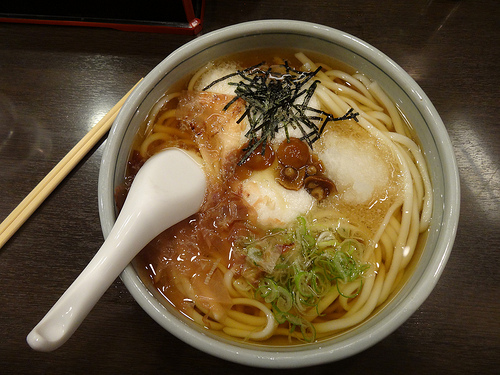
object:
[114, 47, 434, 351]
food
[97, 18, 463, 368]
bowl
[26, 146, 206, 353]
spoon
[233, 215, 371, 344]
onions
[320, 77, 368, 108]
noodles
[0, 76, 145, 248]
chopsticks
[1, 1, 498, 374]
table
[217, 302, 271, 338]
noodles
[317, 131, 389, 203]
cream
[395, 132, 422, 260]
noodles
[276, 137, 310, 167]
mushroom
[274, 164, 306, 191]
mushroom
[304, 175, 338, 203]
mushroom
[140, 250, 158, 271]
broth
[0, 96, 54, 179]
reflection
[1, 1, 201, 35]
tray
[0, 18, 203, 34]
edge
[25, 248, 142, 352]
handle